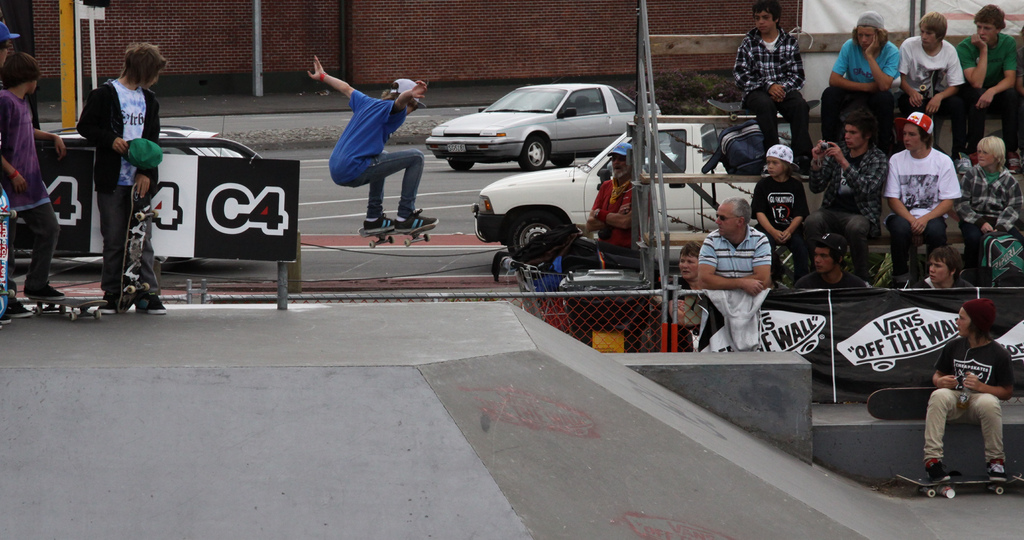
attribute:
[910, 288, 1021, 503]
person — sitting, watching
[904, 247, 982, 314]
person — watching, sitting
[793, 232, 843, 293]
person — sitting, watching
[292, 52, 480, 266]
skateboarder — sitting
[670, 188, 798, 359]
person — watching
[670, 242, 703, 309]
person — sitting, watching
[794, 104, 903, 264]
person — watching, sitting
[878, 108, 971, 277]
person — sitting, watching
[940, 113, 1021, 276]
person — watching, sitting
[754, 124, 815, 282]
person — sitting, watching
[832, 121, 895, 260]
person — sitting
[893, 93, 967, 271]
person — sitting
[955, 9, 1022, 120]
person — sitting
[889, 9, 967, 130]
person — sitting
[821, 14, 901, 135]
person — sitting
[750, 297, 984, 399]
signs — advertising, Vans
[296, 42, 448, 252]
skateboarder — air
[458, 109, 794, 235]
truck — white, parked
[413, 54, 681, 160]
car — silver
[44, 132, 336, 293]
signs — C4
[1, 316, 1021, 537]
ramp — grey, skateboard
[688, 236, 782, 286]
shirt — stripes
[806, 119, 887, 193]
guy — taking